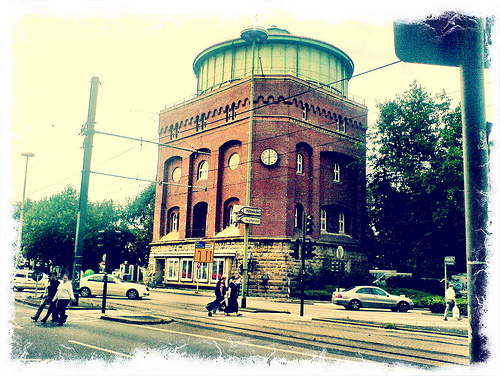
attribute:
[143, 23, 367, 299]
building — oddly shaped, red, brick, large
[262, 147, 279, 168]
clock — large, circular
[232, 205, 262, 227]
street sign — directional, white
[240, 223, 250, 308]
pole — gree, tall, grey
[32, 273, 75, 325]
people — walking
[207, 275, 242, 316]
people — walking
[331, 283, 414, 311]
car — grey, small, parked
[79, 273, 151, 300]
car — white, small, beige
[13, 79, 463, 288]
trees — healthy, green, leafy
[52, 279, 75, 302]
sweater — white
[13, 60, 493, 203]
wires — black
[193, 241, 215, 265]
sign — small, yellow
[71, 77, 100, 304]
telephone pole — wooden, large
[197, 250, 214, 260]
arrows — black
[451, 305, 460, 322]
bag — white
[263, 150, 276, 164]
face — white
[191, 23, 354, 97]
top — round